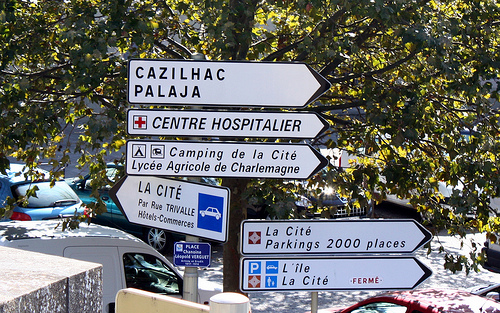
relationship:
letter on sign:
[133, 64, 143, 79] [126, 58, 332, 109]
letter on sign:
[145, 65, 154, 84] [126, 58, 332, 109]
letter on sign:
[156, 65, 169, 77] [126, 58, 332, 109]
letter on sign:
[169, 66, 176, 81] [126, 58, 332, 109]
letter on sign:
[177, 65, 187, 81] [124, 50, 328, 109]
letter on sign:
[189, 65, 200, 79] [126, 58, 332, 109]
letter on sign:
[156, 85, 164, 97] [126, 58, 332, 109]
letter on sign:
[178, 83, 187, 98] [124, 50, 328, 109]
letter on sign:
[230, 117, 240, 133] [118, 104, 328, 144]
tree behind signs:
[323, 17, 470, 168] [117, 51, 429, 291]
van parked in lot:
[2, 213, 186, 300] [2, 182, 484, 307]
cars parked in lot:
[3, 159, 131, 229] [5, 169, 484, 310]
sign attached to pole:
[126, 58, 332, 109] [220, 171, 244, 294]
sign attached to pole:
[124, 104, 332, 141] [214, 172, 246, 292]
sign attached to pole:
[124, 138, 330, 182] [219, 172, 250, 291]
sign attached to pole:
[238, 214, 436, 255] [307, 289, 320, 311]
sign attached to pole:
[237, 254, 435, 290] [307, 289, 322, 311]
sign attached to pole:
[108, 172, 232, 245] [182, 232, 202, 302]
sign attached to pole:
[172, 237, 213, 268] [180, 233, 203, 299]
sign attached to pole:
[126, 56, 334, 109] [218, 175, 249, 288]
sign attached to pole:
[124, 104, 332, 141] [219, 172, 250, 291]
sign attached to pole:
[124, 138, 330, 182] [220, 178, 250, 296]